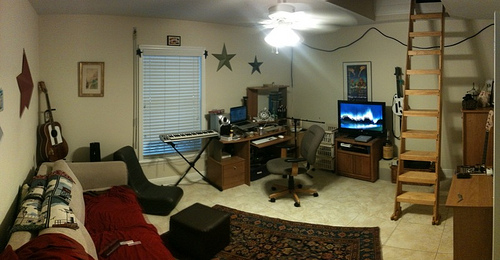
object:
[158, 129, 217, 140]
keyboard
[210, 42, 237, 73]
star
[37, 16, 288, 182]
wall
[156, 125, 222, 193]
piano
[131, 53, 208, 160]
window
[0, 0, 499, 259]
room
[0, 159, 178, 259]
furniture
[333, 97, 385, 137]
television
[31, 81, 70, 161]
guitar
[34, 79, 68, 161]
stand